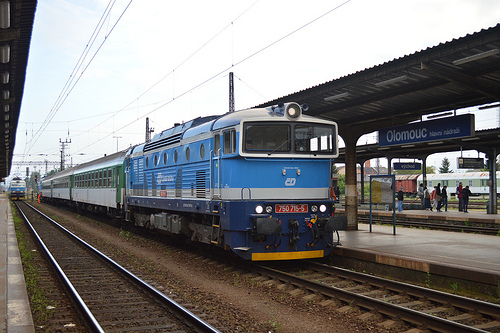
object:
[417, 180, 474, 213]
people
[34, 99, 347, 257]
train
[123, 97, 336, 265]
compartment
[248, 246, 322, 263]
yellow bumper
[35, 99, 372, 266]
train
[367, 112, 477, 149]
sign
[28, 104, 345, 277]
train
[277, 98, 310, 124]
top light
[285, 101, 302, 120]
headlight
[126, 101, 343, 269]
train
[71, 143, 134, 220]
car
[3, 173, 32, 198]
train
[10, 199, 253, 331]
tracks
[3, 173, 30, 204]
train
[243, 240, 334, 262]
stripe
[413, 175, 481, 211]
people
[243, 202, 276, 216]
headlight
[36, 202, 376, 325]
ground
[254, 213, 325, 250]
wires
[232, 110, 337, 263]
train front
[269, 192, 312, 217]
plate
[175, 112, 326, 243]
car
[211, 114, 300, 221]
train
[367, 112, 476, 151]
blue sign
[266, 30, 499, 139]
roof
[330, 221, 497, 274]
platform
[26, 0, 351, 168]
cable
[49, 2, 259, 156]
cable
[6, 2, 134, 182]
cable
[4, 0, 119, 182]
cable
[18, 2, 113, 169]
cable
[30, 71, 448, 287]
train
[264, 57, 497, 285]
train station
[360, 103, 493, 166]
sign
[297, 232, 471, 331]
rail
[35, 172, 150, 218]
train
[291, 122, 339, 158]
window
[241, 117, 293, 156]
window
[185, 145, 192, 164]
window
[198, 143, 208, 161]
window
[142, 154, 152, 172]
window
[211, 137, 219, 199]
door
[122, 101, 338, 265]
blue engine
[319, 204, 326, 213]
headlight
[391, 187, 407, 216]
person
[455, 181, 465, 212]
person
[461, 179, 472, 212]
person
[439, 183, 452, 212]
person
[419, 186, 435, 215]
person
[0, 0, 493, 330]
station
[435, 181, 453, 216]
person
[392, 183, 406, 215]
person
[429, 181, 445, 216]
person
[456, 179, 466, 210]
person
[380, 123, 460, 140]
lettering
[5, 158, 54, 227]
background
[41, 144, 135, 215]
cars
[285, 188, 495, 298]
platform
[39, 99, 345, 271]
train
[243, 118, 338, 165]
windows